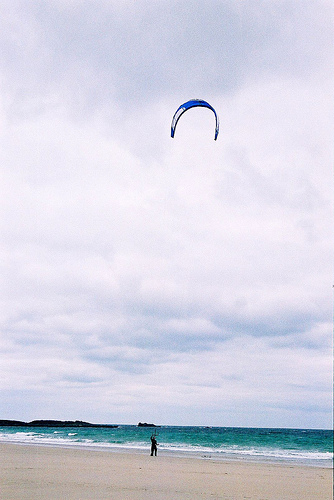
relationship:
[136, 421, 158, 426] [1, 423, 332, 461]
rock in ocean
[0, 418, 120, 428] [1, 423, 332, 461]
rock in ocean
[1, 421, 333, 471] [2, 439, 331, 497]
water near shore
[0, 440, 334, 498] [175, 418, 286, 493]
sand on beach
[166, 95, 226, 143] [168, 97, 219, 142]
kite shaped like boomerang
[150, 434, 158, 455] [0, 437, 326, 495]
man standing on beach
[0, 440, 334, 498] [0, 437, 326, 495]
sand on beach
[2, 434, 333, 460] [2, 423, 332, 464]
spray of water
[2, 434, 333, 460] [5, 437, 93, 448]
spray from wave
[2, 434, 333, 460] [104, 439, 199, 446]
spray from wave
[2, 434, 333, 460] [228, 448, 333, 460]
spray from wave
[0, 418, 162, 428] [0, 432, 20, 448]
jetty at end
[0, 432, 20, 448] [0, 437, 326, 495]
end of beach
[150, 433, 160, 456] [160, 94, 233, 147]
man flying kite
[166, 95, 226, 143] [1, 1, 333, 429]
kite in cloudy sky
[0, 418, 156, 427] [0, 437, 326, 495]
mountains beside beach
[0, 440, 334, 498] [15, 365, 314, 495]
sand on beach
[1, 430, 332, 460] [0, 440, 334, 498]
wave crashing against sand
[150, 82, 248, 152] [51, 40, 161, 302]
object in air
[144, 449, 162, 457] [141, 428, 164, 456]
legs of person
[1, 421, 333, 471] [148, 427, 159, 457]
water next to man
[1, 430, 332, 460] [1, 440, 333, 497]
wave coming to land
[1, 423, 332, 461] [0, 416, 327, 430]
ocean in background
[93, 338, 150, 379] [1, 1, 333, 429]
cloud in cloudy sky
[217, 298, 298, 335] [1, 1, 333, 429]
cloud in cloudy sky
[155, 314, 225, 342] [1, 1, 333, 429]
cloud in cloudy sky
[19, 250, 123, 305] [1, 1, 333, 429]
cloud in cloudy sky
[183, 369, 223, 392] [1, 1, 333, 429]
cloud in cloudy sky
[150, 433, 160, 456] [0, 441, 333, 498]
man on beach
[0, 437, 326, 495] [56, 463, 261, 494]
beach covered in sand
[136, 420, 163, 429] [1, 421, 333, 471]
protrusion in water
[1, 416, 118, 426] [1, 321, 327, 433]
background land in background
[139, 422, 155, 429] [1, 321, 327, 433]
background land in background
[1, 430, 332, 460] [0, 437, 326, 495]
wave breaking on beach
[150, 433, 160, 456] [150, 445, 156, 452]
man dressed in clothing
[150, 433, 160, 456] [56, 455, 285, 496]
man on beach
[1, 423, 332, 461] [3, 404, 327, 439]
ocean at skyline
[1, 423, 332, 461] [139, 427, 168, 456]
ocean behind person